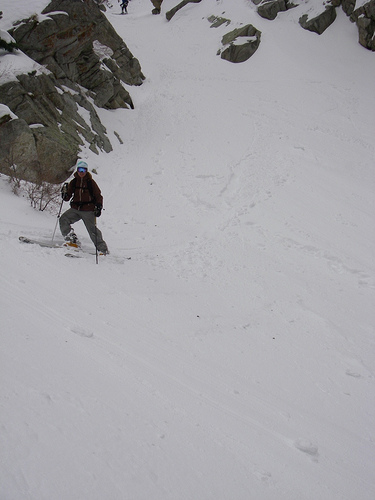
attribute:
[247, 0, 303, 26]
rock — large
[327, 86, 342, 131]
snow — white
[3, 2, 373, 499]
snow — white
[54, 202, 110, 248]
ski pants — grey